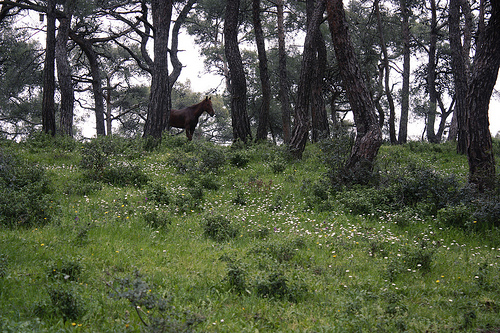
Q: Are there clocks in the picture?
A: No, there are no clocks.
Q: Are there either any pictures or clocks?
A: No, there are no clocks or pictures.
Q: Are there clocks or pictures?
A: No, there are no clocks or pictures.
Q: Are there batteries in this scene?
A: No, there are no batteries.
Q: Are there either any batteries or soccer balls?
A: No, there are no batteries or soccer balls.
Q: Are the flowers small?
A: Yes, the flowers are small.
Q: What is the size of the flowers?
A: The flowers are small.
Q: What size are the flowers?
A: The flowers are small.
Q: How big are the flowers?
A: The flowers are small.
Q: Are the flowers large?
A: No, the flowers are small.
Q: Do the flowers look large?
A: No, the flowers are small.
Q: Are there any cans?
A: No, there are no cans.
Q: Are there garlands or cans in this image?
A: No, there are no cans or garlands.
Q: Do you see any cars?
A: No, there are no cars.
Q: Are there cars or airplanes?
A: No, there are no cars or airplanes.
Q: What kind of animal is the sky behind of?
A: The sky is behind the horse.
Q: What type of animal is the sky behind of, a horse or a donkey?
A: The sky is behind a horse.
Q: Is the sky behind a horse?
A: Yes, the sky is behind a horse.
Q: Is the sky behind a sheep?
A: No, the sky is behind a horse.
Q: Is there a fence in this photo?
A: No, there are no fences.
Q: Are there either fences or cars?
A: No, there are no fences or cars.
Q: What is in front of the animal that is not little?
A: The tree is in front of the horse.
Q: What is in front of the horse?
A: The tree is in front of the horse.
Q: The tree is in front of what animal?
A: The tree is in front of the horse.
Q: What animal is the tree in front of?
A: The tree is in front of the horse.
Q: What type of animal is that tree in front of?
A: The tree is in front of the horse.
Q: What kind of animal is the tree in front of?
A: The tree is in front of the horse.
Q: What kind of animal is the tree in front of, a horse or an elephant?
A: The tree is in front of a horse.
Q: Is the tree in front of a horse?
A: Yes, the tree is in front of a horse.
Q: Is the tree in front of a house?
A: No, the tree is in front of a horse.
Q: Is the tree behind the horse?
A: No, the tree is in front of the horse.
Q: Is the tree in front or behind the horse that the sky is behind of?
A: The tree is in front of the horse.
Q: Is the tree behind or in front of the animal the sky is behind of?
A: The tree is in front of the horse.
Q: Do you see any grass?
A: Yes, there is grass.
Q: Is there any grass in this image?
A: Yes, there is grass.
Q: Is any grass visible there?
A: Yes, there is grass.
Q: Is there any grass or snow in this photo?
A: Yes, there is grass.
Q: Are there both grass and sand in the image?
A: No, there is grass but no sand.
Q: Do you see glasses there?
A: No, there are no glasses.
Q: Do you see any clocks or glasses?
A: No, there are no glasses or clocks.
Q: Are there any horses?
A: Yes, there is a horse.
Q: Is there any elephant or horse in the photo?
A: Yes, there is a horse.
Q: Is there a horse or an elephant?
A: Yes, there is a horse.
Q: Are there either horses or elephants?
A: Yes, there is a horse.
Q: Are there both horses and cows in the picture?
A: No, there is a horse but no cows.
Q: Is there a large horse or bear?
A: Yes, there is a large horse.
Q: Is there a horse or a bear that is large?
A: Yes, the horse is large.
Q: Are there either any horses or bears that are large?
A: Yes, the horse is large.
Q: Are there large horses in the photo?
A: Yes, there is a large horse.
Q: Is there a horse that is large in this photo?
A: Yes, there is a large horse.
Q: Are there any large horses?
A: Yes, there is a large horse.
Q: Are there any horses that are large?
A: Yes, there is a horse that is large.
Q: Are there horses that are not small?
A: Yes, there is a large horse.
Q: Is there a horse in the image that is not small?
A: Yes, there is a large horse.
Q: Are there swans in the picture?
A: No, there are no swans.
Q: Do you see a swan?
A: No, there are no swans.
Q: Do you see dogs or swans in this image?
A: No, there are no swans or dogs.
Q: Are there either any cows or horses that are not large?
A: No, there is a horse but it is large.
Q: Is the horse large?
A: Yes, the horse is large.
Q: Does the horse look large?
A: Yes, the horse is large.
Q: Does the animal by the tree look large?
A: Yes, the horse is large.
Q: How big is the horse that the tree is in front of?
A: The horse is large.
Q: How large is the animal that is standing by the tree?
A: The horse is large.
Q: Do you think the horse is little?
A: No, the horse is large.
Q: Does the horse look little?
A: No, the horse is large.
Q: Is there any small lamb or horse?
A: No, there is a horse but it is large.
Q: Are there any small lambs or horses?
A: No, there is a horse but it is large.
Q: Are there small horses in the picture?
A: No, there is a horse but it is large.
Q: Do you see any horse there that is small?
A: No, there is a horse but it is large.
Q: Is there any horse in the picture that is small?
A: No, there is a horse but it is large.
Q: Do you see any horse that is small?
A: No, there is a horse but it is large.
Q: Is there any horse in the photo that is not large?
A: No, there is a horse but it is large.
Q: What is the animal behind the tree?
A: The animal is a horse.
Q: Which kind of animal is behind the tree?
A: The animal is a horse.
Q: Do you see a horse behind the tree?
A: Yes, there is a horse behind the tree.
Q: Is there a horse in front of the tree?
A: No, the horse is behind the tree.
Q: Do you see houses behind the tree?
A: No, there is a horse behind the tree.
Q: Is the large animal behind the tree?
A: Yes, the horse is behind the tree.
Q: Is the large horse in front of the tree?
A: No, the horse is behind the tree.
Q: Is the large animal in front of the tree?
A: No, the horse is behind the tree.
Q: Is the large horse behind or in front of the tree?
A: The horse is behind the tree.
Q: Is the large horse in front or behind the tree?
A: The horse is behind the tree.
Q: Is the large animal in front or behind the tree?
A: The horse is behind the tree.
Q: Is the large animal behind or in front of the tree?
A: The horse is behind the tree.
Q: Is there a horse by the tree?
A: Yes, there is a horse by the tree.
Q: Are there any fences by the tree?
A: No, there is a horse by the tree.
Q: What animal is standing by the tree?
A: The horse is standing by the tree.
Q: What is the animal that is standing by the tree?
A: The animal is a horse.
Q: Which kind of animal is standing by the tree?
A: The animal is a horse.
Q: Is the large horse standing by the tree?
A: Yes, the horse is standing by the tree.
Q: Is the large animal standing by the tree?
A: Yes, the horse is standing by the tree.